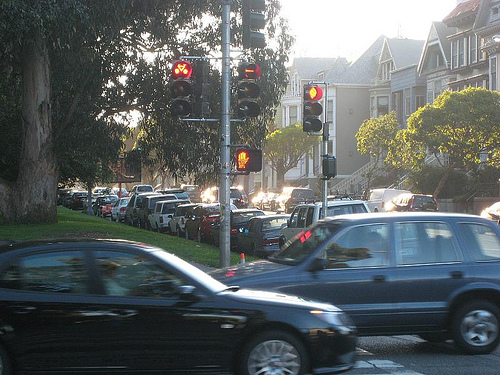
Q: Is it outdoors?
A: Yes, it is outdoors.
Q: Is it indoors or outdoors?
A: It is outdoors.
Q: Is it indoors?
A: No, it is outdoors.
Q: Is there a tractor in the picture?
A: No, there are no tractors.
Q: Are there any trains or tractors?
A: No, there are no tractors or trains.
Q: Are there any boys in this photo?
A: No, there are no boys.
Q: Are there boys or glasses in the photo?
A: No, there are no boys or glasses.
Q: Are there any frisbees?
A: No, there are no frisbees.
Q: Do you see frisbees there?
A: No, there are no frisbees.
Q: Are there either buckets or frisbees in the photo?
A: No, there are no frisbees or buckets.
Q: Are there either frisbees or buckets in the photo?
A: No, there are no frisbees or buckets.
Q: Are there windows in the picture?
A: Yes, there is a window.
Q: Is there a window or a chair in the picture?
A: Yes, there is a window.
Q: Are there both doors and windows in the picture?
A: No, there is a window but no doors.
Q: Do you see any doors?
A: No, there are no doors.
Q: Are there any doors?
A: No, there are no doors.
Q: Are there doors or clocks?
A: No, there are no doors or clocks.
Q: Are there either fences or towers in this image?
A: No, there are no fences or towers.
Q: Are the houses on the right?
A: Yes, the houses are on the right of the image.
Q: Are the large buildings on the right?
A: Yes, the houses are on the right of the image.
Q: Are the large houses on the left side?
A: No, the houses are on the right of the image.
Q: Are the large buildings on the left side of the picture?
A: No, the houses are on the right of the image.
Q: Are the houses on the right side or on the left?
A: The houses are on the right of the image.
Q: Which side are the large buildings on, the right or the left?
A: The houses are on the right of the image.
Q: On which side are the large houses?
A: The houses are on the right of the image.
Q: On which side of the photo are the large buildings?
A: The houses are on the right of the image.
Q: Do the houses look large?
A: Yes, the houses are large.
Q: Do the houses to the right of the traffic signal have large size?
A: Yes, the houses are large.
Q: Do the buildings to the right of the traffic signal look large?
A: Yes, the houses are large.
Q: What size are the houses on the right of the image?
A: The houses are large.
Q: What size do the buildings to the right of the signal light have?
A: The houses have large size.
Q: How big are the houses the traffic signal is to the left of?
A: The houses are large.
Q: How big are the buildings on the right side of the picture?
A: The houses are large.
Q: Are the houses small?
A: No, the houses are large.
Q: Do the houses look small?
A: No, the houses are large.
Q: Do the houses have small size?
A: No, the houses are large.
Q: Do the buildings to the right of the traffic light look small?
A: No, the houses are large.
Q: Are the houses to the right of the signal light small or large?
A: The houses are large.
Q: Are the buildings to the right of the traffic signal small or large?
A: The houses are large.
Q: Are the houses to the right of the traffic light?
A: Yes, the houses are to the right of the traffic light.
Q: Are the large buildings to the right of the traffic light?
A: Yes, the houses are to the right of the traffic light.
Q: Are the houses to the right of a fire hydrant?
A: No, the houses are to the right of the traffic light.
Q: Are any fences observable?
A: No, there are no fences.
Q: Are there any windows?
A: Yes, there is a window.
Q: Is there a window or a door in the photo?
A: Yes, there is a window.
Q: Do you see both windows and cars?
A: Yes, there are both a window and a car.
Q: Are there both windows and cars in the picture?
A: Yes, there are both a window and a car.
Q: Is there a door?
A: No, there are no doors.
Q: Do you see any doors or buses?
A: No, there are no doors or buses.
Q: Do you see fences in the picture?
A: No, there are no fences.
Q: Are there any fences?
A: No, there are no fences.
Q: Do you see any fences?
A: No, there are no fences.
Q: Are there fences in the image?
A: No, there are no fences.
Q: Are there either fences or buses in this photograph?
A: No, there are no fences or buses.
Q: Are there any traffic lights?
A: Yes, there is a traffic light.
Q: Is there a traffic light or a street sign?
A: Yes, there is a traffic light.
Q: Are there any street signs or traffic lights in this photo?
A: Yes, there is a traffic light.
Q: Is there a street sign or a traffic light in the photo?
A: Yes, there is a traffic light.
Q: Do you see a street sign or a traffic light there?
A: Yes, there is a traffic light.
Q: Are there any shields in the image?
A: No, there are no shields.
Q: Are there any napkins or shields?
A: No, there are no shields or napkins.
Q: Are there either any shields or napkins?
A: No, there are no shields or napkins.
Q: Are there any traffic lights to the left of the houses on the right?
A: Yes, there is a traffic light to the left of the houses.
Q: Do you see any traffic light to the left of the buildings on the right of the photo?
A: Yes, there is a traffic light to the left of the houses.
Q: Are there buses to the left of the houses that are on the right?
A: No, there is a traffic light to the left of the houses.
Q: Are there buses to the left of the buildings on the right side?
A: No, there is a traffic light to the left of the houses.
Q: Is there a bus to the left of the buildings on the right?
A: No, there is a traffic light to the left of the houses.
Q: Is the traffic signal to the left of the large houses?
A: Yes, the traffic signal is to the left of the houses.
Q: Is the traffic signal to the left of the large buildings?
A: Yes, the traffic signal is to the left of the houses.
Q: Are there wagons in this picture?
A: No, there are no wagons.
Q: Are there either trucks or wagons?
A: No, there are no wagons or trucks.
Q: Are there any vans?
A: No, there are no vans.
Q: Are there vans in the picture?
A: No, there are no vans.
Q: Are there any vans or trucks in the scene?
A: No, there are no vans or trucks.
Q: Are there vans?
A: No, there are no vans.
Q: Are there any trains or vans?
A: No, there are no vans or trains.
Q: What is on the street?
A: The car is on the street.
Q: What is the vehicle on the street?
A: The vehicle is a car.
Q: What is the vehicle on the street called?
A: The vehicle is a car.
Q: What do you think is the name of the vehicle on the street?
A: The vehicle is a car.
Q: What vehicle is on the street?
A: The vehicle is a car.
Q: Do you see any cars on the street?
A: Yes, there is a car on the street.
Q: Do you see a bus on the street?
A: No, there is a car on the street.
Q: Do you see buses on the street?
A: No, there is a car on the street.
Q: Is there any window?
A: Yes, there is a window.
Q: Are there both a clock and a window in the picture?
A: No, there is a window but no clocks.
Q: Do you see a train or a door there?
A: No, there are no doors or trains.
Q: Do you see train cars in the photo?
A: No, there are no train cars.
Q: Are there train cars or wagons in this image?
A: No, there are no train cars or wagons.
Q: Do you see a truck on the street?
A: No, there is a car on the street.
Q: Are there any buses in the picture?
A: No, there are no buses.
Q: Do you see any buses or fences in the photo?
A: No, there are no buses or fences.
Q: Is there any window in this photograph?
A: Yes, there is a window.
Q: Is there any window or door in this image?
A: Yes, there is a window.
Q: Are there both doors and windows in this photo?
A: No, there is a window but no doors.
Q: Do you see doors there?
A: No, there are no doors.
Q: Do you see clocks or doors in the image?
A: No, there are no doors or clocks.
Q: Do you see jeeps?
A: No, there are no jeeps.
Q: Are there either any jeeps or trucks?
A: No, there are no jeeps or trucks.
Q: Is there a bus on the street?
A: No, there is a car on the street.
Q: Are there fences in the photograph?
A: No, there are no fences.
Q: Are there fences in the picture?
A: No, there are no fences.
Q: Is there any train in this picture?
A: No, there are no trains.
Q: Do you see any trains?
A: No, there are no trains.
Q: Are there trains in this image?
A: No, there are no trains.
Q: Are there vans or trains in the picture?
A: No, there are no trains or vans.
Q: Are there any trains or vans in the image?
A: No, there are no trains or vans.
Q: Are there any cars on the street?
A: Yes, there is a car on the street.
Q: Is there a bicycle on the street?
A: No, there is a car on the street.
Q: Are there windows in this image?
A: Yes, there is a window.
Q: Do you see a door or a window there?
A: Yes, there is a window.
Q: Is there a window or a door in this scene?
A: Yes, there is a window.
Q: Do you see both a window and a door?
A: No, there is a window but no doors.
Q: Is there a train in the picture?
A: No, there are no trains.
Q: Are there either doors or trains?
A: No, there are no trains or doors.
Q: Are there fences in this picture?
A: No, there are no fences.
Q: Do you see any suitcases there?
A: No, there are no suitcases.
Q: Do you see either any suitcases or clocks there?
A: No, there are no suitcases or clocks.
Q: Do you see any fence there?
A: No, there are no fences.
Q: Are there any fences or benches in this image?
A: No, there are no fences or benches.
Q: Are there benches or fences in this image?
A: No, there are no fences or benches.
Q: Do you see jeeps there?
A: No, there are no jeeps.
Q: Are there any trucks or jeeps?
A: No, there are no jeeps or trucks.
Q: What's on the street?
A: The car is on the street.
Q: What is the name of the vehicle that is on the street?
A: The vehicle is a car.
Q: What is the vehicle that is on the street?
A: The vehicle is a car.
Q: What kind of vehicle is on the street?
A: The vehicle is a car.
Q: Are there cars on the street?
A: Yes, there is a car on the street.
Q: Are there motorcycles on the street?
A: No, there is a car on the street.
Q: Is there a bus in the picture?
A: No, there are no buses.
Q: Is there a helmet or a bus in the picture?
A: No, there are no buses or helmets.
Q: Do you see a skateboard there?
A: No, there are no skateboards.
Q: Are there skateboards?
A: No, there are no skateboards.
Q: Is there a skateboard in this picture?
A: No, there are no skateboards.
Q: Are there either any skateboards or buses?
A: No, there are no skateboards or buses.